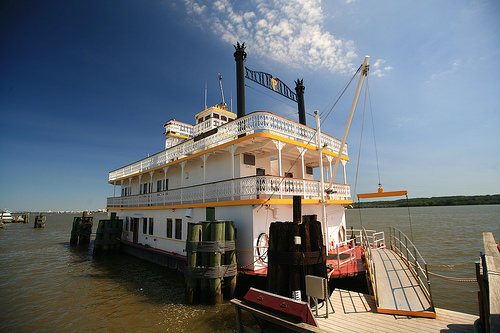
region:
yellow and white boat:
[98, 111, 361, 275]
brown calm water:
[42, 246, 147, 324]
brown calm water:
[413, 210, 466, 246]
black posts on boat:
[226, 40, 324, 112]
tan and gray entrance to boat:
[346, 230, 437, 322]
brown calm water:
[13, 225, 60, 279]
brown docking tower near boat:
[240, 196, 349, 294]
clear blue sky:
[15, 15, 159, 132]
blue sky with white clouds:
[404, 23, 479, 164]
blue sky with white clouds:
[177, 3, 362, 38]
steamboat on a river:
[40, 18, 467, 328]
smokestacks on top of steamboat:
[218, 29, 310, 126]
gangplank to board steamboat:
[356, 223, 452, 330]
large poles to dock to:
[63, 208, 241, 304]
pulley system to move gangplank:
[333, 56, 420, 255]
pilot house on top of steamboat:
[176, 84, 242, 141]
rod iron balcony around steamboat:
[101, 177, 358, 204]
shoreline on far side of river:
[363, 193, 498, 219]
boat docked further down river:
[1, 200, 21, 234]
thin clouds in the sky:
[198, 2, 386, 89]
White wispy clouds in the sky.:
[184, 2, 399, 89]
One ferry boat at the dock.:
[81, 57, 386, 285]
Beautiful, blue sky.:
[10, 10, 165, 164]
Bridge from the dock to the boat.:
[345, 223, 438, 320]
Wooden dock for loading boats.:
[215, 258, 497, 331]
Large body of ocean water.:
[382, 198, 492, 310]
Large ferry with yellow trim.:
[98, 97, 374, 302]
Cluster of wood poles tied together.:
[64, 202, 96, 254]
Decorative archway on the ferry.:
[225, 36, 312, 134]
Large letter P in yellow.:
[270, 66, 285, 98]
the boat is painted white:
[110, 108, 377, 285]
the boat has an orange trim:
[107, 131, 348, 186]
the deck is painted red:
[231, 236, 384, 283]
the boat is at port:
[106, 105, 396, 289]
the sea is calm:
[3, 198, 498, 330]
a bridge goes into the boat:
[358, 221, 440, 316]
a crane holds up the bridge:
[361, 54, 426, 279]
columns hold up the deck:
[273, 138, 288, 196]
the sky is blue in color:
[2, 1, 497, 206]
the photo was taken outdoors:
[0, 0, 499, 331]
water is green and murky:
[25, 233, 102, 331]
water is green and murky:
[56, 272, 132, 327]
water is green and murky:
[37, 262, 116, 317]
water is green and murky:
[86, 282, 159, 332]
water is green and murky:
[69, 255, 147, 321]